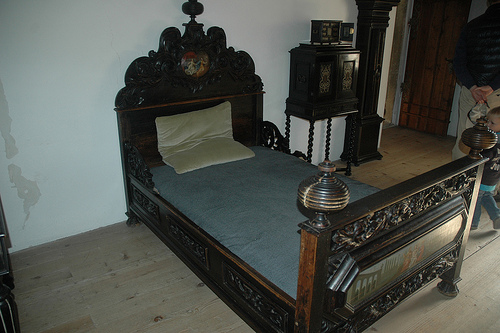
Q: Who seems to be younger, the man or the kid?
A: The kid is younger than the man.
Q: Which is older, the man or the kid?
A: The man is older than the kid.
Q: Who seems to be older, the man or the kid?
A: The man is older than the kid.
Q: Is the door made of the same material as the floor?
A: Yes, both the door and the floor are made of wood.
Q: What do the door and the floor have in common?
A: The material, both the door and the floor are wooden.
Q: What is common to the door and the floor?
A: The material, both the door and the floor are wooden.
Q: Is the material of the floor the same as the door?
A: Yes, both the floor and the door are made of wood.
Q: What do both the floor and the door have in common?
A: The material, both the floor and the door are wooden.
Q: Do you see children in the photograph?
A: Yes, there is a child.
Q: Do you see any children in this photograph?
A: Yes, there is a child.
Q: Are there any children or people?
A: Yes, there is a child.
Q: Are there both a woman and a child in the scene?
A: No, there is a child but no women.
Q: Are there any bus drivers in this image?
A: No, there are no bus drivers.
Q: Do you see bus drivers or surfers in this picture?
A: No, there are no bus drivers or surfers.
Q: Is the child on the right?
A: Yes, the child is on the right of the image.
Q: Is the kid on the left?
A: No, the kid is on the right of the image.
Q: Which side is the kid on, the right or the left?
A: The kid is on the right of the image.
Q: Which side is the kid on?
A: The kid is on the right of the image.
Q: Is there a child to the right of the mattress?
A: Yes, there is a child to the right of the mattress.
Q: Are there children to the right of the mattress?
A: Yes, there is a child to the right of the mattress.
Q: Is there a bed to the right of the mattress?
A: No, there is a child to the right of the mattress.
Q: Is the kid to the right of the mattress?
A: Yes, the kid is to the right of the mattress.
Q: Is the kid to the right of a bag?
A: No, the kid is to the right of the mattress.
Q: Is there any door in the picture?
A: Yes, there is a door.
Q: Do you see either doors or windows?
A: Yes, there is a door.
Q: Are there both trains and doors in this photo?
A: No, there is a door but no trains.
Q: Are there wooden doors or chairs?
A: Yes, there is a wood door.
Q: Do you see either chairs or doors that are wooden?
A: Yes, the door is wooden.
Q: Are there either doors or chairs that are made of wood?
A: Yes, the door is made of wood.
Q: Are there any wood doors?
A: Yes, there is a wood door.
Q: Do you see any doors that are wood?
A: Yes, there is a wood door.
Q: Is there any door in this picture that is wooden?
A: Yes, there is a door that is wooden.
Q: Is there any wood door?
A: Yes, there is a door that is made of wood.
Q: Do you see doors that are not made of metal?
A: Yes, there is a door that is made of wood.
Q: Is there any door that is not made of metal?
A: Yes, there is a door that is made of wood.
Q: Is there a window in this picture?
A: No, there are no windows.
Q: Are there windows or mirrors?
A: No, there are no windows or mirrors.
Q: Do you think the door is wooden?
A: Yes, the door is wooden.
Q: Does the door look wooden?
A: Yes, the door is wooden.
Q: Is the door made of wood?
A: Yes, the door is made of wood.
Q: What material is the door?
A: The door is made of wood.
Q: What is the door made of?
A: The door is made of wood.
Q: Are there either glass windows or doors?
A: No, there is a door but it is wooden.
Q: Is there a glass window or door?
A: No, there is a door but it is wooden.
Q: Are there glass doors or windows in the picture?
A: No, there is a door but it is wooden.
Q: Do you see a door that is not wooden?
A: No, there is a door but it is wooden.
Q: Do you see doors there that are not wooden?
A: No, there is a door but it is wooden.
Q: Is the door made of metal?
A: No, the door is made of wood.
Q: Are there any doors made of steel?
A: No, there is a door but it is made of wood.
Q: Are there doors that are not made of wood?
A: No, there is a door but it is made of wood.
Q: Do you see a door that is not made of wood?
A: No, there is a door but it is made of wood.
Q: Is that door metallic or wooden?
A: The door is wooden.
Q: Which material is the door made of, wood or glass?
A: The door is made of wood.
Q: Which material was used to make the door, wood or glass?
A: The door is made of wood.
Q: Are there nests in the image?
A: No, there are no nests.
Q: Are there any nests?
A: No, there are no nests.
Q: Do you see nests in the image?
A: No, there are no nests.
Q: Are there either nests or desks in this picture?
A: No, there are no nests or desks.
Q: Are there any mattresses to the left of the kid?
A: Yes, there is a mattress to the left of the kid.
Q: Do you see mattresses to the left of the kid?
A: Yes, there is a mattress to the left of the kid.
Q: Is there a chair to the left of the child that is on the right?
A: No, there is a mattress to the left of the kid.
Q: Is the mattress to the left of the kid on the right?
A: Yes, the mattress is to the left of the child.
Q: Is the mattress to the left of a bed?
A: No, the mattress is to the left of the child.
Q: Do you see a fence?
A: No, there are no fences.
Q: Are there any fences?
A: No, there are no fences.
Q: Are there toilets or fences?
A: No, there are no fences or toilets.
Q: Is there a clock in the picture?
A: Yes, there is a clock.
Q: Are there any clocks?
A: Yes, there is a clock.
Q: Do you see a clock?
A: Yes, there is a clock.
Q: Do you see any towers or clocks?
A: Yes, there is a clock.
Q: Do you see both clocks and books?
A: No, there is a clock but no books.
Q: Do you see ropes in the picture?
A: No, there are no ropes.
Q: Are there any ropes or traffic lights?
A: No, there are no ropes or traffic lights.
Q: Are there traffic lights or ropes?
A: No, there are no ropes or traffic lights.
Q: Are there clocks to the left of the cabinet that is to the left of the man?
A: Yes, there is a clock to the left of the cabinet.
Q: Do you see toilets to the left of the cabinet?
A: No, there is a clock to the left of the cabinet.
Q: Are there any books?
A: No, there are no books.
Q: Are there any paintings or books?
A: No, there are no books or paintings.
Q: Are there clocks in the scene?
A: Yes, there is a clock.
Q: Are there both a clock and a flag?
A: No, there is a clock but no flags.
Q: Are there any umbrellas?
A: No, there are no umbrellas.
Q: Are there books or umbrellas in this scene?
A: No, there are no umbrellas or books.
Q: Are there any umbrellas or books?
A: No, there are no umbrellas or books.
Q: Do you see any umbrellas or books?
A: No, there are no umbrellas or books.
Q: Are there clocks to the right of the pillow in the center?
A: Yes, there is a clock to the right of the pillow.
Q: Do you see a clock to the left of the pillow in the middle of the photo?
A: No, the clock is to the right of the pillow.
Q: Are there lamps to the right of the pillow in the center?
A: No, there is a clock to the right of the pillow.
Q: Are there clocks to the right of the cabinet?
A: Yes, there is a clock to the right of the cabinet.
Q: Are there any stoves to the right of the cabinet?
A: No, there is a clock to the right of the cabinet.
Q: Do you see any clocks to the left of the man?
A: Yes, there is a clock to the left of the man.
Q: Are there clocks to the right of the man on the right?
A: No, the clock is to the left of the man.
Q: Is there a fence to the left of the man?
A: No, there is a clock to the left of the man.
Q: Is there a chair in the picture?
A: No, there are no chairs.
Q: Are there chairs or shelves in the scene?
A: No, there are no chairs or shelves.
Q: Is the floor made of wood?
A: Yes, the floor is made of wood.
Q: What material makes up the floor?
A: The floor is made of wood.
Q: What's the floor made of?
A: The floor is made of wood.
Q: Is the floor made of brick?
A: No, the floor is made of wood.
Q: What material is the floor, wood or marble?
A: The floor is made of wood.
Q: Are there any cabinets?
A: Yes, there is a cabinet.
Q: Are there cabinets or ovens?
A: Yes, there is a cabinet.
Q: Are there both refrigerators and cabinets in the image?
A: No, there is a cabinet but no refrigerators.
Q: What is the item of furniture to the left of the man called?
A: The piece of furniture is a cabinet.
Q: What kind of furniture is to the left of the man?
A: The piece of furniture is a cabinet.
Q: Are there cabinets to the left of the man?
A: Yes, there is a cabinet to the left of the man.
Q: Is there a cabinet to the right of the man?
A: No, the cabinet is to the left of the man.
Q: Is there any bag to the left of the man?
A: No, there is a cabinet to the left of the man.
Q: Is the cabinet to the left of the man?
A: Yes, the cabinet is to the left of the man.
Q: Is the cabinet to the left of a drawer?
A: No, the cabinet is to the left of the man.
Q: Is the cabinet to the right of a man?
A: No, the cabinet is to the left of a man.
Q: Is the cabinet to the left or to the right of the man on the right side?
A: The cabinet is to the left of the man.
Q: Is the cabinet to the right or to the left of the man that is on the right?
A: The cabinet is to the left of the man.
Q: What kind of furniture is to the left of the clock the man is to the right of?
A: The piece of furniture is a cabinet.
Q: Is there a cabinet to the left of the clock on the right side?
A: Yes, there is a cabinet to the left of the clock.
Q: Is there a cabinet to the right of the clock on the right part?
A: No, the cabinet is to the left of the clock.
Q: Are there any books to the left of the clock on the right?
A: No, there is a cabinet to the left of the clock.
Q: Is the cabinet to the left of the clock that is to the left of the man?
A: Yes, the cabinet is to the left of the clock.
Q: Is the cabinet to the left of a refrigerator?
A: No, the cabinet is to the left of the clock.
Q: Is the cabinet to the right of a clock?
A: No, the cabinet is to the left of a clock.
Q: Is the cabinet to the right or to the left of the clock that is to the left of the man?
A: The cabinet is to the left of the clock.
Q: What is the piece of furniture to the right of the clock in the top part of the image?
A: The piece of furniture is a cabinet.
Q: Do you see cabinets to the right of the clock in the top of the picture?
A: Yes, there is a cabinet to the right of the clock.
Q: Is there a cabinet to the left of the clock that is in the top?
A: No, the cabinet is to the right of the clock.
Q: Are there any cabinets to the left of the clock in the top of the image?
A: No, the cabinet is to the right of the clock.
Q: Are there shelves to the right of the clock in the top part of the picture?
A: No, there is a cabinet to the right of the clock.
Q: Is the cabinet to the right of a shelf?
A: No, the cabinet is to the right of a clock.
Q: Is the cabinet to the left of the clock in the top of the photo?
A: No, the cabinet is to the right of the clock.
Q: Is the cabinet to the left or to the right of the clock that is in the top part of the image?
A: The cabinet is to the right of the clock.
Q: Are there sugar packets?
A: No, there are no sugar packets.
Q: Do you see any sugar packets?
A: No, there are no sugar packets.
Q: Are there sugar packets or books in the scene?
A: No, there are no sugar packets or books.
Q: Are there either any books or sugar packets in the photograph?
A: No, there are no sugar packets or books.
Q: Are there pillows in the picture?
A: Yes, there is a pillow.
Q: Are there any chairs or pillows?
A: Yes, there is a pillow.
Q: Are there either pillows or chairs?
A: Yes, there is a pillow.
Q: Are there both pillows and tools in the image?
A: No, there is a pillow but no tools.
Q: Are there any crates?
A: No, there are no crates.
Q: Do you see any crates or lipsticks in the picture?
A: No, there are no crates or lipsticks.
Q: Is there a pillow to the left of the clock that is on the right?
A: Yes, there is a pillow to the left of the clock.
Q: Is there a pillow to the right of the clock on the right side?
A: No, the pillow is to the left of the clock.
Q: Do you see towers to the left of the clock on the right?
A: No, there is a pillow to the left of the clock.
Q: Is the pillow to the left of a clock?
A: Yes, the pillow is to the left of a clock.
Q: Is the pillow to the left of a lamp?
A: No, the pillow is to the left of a clock.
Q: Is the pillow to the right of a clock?
A: No, the pillow is to the left of a clock.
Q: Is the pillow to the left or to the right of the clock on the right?
A: The pillow is to the left of the clock.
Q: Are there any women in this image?
A: No, there are no women.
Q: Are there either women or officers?
A: No, there are no women or officers.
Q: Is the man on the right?
A: Yes, the man is on the right of the image.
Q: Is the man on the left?
A: No, the man is on the right of the image.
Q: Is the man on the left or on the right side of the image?
A: The man is on the right of the image.